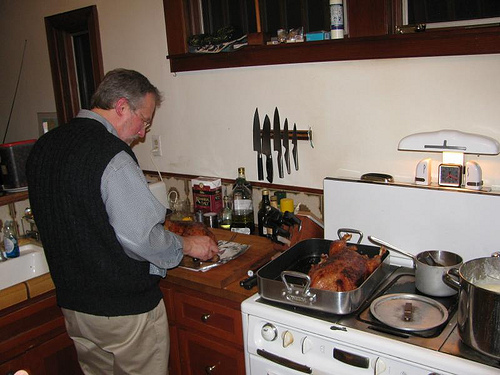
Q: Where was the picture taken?
A: A kitchen.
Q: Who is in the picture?
A: A man.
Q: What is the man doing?
A: Cooking.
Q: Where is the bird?
A: In the pan.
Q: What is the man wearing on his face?
A: Glasses.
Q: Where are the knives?
A: On the wall.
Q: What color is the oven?
A: White.